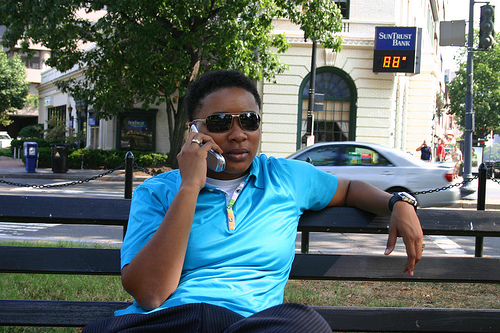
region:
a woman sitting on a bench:
[112, 72, 424, 331]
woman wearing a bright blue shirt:
[117, 151, 337, 321]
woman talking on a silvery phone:
[177, 121, 225, 184]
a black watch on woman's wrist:
[383, 188, 418, 212]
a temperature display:
[372, 26, 422, 71]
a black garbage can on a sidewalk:
[49, 144, 71, 175]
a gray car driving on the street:
[285, 135, 460, 207]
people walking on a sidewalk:
[416, 137, 463, 163]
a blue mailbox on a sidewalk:
[23, 141, 38, 173]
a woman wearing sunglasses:
[193, 110, 262, 133]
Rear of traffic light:
[477, 2, 495, 54]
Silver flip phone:
[183, 123, 225, 176]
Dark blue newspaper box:
[22, 138, 41, 173]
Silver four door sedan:
[285, 138, 459, 208]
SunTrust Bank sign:
[375, 28, 419, 53]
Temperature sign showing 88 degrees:
[372, 50, 414, 72]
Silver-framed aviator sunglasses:
[185, 111, 274, 134]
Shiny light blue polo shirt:
[116, 163, 343, 313]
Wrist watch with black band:
[382, 185, 422, 216]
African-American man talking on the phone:
[119, 73, 356, 331]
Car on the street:
[285, 139, 462, 205]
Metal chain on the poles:
[1, 150, 498, 255]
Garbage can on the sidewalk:
[50, 144, 70, 174]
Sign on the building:
[372, 24, 421, 75]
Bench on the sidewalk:
[0, 191, 495, 331]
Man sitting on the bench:
[103, 68, 423, 332]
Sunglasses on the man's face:
[180, 109, 261, 133]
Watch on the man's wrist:
[386, 190, 420, 211]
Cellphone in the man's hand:
[185, 123, 227, 174]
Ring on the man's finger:
[187, 137, 201, 143]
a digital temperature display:
[369, 48, 416, 76]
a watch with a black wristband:
[383, 188, 418, 216]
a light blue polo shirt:
[121, 155, 342, 317]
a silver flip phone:
[181, 123, 228, 172]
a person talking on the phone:
[111, 59, 450, 331]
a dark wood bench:
[1, 190, 498, 331]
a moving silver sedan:
[278, 140, 463, 212]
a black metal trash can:
[47, 142, 72, 177]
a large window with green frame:
[291, 63, 363, 153]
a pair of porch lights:
[61, 98, 88, 124]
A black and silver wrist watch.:
[389, 188, 420, 215]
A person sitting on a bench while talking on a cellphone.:
[97, 68, 431, 331]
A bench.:
[1, 190, 498, 331]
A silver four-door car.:
[287, 139, 462, 219]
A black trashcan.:
[53, 143, 67, 178]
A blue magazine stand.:
[22, 142, 40, 172]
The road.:
[1, 174, 497, 242]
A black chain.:
[2, 160, 497, 197]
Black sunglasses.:
[187, 112, 264, 134]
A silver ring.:
[190, 134, 202, 145]